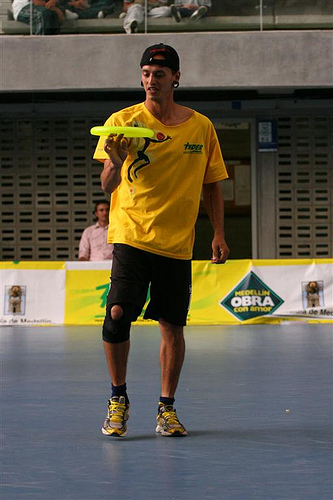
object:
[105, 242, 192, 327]
shorts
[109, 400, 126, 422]
lace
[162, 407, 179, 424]
lace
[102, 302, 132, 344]
brace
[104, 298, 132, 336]
knee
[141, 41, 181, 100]
head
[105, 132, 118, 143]
finger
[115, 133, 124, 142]
finger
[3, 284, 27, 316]
logo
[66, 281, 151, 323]
logo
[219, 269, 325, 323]
logo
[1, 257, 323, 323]
wall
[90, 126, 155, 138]
frisbee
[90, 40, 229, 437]
trick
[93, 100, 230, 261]
shirt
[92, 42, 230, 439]
man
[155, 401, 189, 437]
shoe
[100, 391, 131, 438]
foot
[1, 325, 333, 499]
ground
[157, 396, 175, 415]
sock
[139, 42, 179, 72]
back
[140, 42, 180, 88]
cap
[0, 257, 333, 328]
banner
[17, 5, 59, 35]
jeans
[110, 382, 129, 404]
sock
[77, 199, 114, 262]
man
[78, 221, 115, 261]
shirt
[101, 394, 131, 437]
shoe